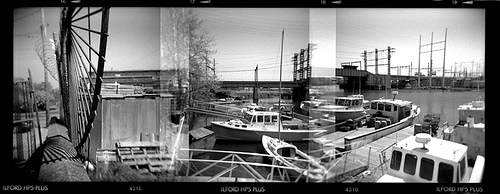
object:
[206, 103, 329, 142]
ship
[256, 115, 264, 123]
window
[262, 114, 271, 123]
window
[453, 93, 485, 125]
boat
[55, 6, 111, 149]
wheel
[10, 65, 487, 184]
pier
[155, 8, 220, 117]
tree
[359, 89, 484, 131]
water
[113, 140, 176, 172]
pallets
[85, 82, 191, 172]
building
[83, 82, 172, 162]
shack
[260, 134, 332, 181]
boat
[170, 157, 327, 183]
fencing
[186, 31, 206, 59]
branch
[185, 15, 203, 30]
branch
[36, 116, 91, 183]
rail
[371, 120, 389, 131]
box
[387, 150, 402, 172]
window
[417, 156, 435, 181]
window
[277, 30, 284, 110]
power pole